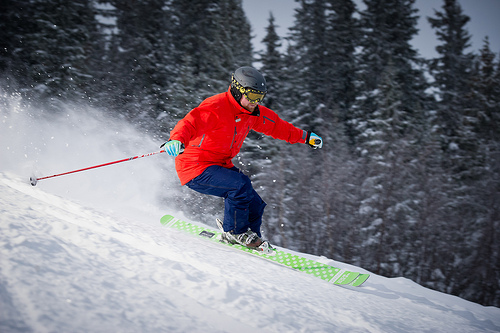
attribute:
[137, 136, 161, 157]
top — white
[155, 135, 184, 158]
gloves — blue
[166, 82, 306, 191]
jacket — red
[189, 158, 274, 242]
jeans — blue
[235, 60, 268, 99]
helmet — gray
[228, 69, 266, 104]
google — yellow, black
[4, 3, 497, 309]
snow covered trees — snow-covered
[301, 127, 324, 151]
pair of googles — yellow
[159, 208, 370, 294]
green ski on snow — white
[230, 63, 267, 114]
gray helmet on head — grey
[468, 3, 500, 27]
sky is blue — daytime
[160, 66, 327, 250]
person skiing — downhill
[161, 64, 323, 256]
person in blue pant — snow pants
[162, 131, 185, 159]
blue & yellow gloves — ski gloves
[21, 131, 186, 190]
downhill ski pole — ski pole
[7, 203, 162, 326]
snow is visible — white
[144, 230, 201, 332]
snow is visible — white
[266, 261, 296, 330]
snow is visible — white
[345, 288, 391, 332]
snow is visible — white